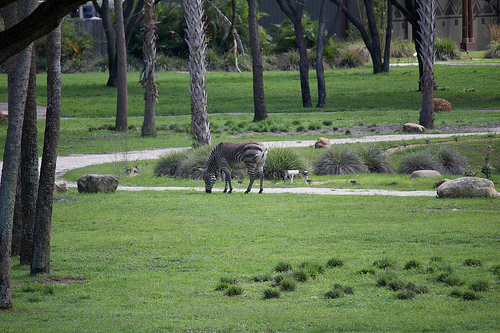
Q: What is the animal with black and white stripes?
A: Zebra.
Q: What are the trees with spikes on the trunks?
A: Palm trees.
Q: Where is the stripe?
A: On the zebra.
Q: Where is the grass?
A: On the ground.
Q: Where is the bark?
A: On the tree.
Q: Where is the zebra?
A: In the grass.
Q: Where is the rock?
A: On the ground.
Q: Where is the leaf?
A: On the plant.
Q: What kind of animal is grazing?
A: Zebra.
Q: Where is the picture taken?
A: Zoo.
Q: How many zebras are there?
A: One.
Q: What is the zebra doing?
A: Grazing on grass.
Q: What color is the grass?
A: Green.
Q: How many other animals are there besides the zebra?
A: None.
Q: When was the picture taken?
A: Spring.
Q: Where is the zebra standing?
A: On the grass.